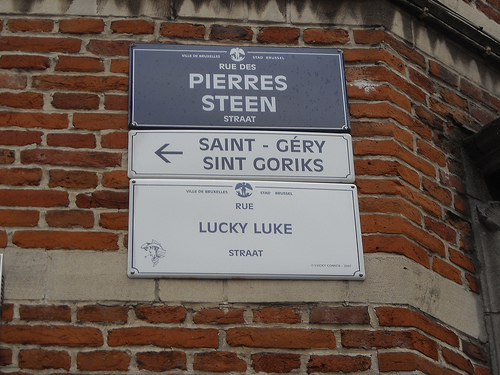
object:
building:
[0, 0, 498, 373]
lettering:
[185, 70, 291, 115]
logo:
[141, 239, 168, 266]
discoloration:
[339, 73, 389, 93]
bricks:
[23, 137, 117, 177]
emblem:
[233, 180, 252, 199]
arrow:
[154, 142, 183, 163]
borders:
[129, 131, 358, 184]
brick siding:
[0, 15, 80, 90]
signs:
[122, 175, 360, 281]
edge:
[436, 88, 496, 234]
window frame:
[468, 182, 496, 309]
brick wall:
[373, 323, 490, 367]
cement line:
[2, 248, 489, 341]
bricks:
[0, 312, 79, 335]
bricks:
[171, 314, 242, 374]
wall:
[4, 20, 493, 371]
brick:
[419, 172, 455, 208]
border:
[126, 40, 352, 133]